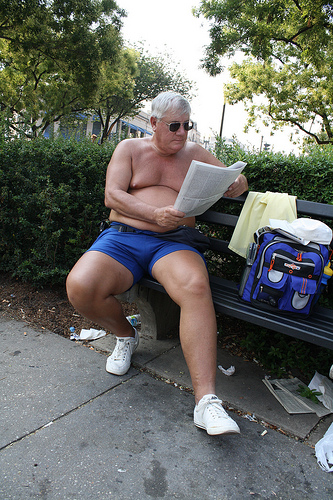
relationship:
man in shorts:
[65, 90, 249, 437] [85, 220, 207, 284]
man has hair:
[65, 90, 249, 437] [149, 89, 189, 117]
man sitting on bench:
[65, 90, 249, 437] [136, 200, 329, 342]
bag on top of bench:
[239, 219, 328, 318] [136, 200, 329, 342]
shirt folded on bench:
[226, 189, 298, 259] [136, 200, 329, 342]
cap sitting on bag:
[271, 218, 331, 244] [239, 219, 328, 318]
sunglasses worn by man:
[154, 117, 195, 131] [65, 90, 249, 437]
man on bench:
[65, 90, 249, 437] [136, 200, 329, 342]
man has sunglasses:
[65, 90, 249, 437] [154, 117, 195, 131]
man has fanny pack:
[65, 90, 249, 437] [102, 220, 210, 249]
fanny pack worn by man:
[102, 220, 210, 249] [65, 90, 249, 437]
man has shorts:
[65, 90, 249, 437] [85, 220, 207, 284]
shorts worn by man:
[85, 220, 207, 284] [65, 90, 249, 437]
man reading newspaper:
[65, 90, 249, 437] [171, 158, 249, 219]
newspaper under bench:
[261, 371, 332, 419] [136, 200, 329, 342]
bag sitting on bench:
[239, 219, 328, 318] [136, 200, 329, 342]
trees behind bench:
[193, 0, 333, 152] [136, 200, 329, 342]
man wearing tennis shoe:
[65, 90, 249, 437] [191, 393, 238, 435]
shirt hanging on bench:
[226, 189, 298, 259] [136, 200, 329, 342]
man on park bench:
[65, 90, 249, 437] [136, 200, 329, 342]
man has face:
[65, 90, 249, 437] [156, 113, 188, 150]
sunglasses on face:
[154, 117, 195, 131] [156, 113, 188, 150]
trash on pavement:
[219, 363, 332, 417] [3, 279, 332, 498]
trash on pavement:
[63, 322, 106, 344] [3, 279, 332, 498]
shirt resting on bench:
[226, 189, 298, 259] [136, 200, 329, 342]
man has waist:
[65, 90, 249, 437] [92, 216, 212, 251]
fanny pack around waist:
[102, 220, 210, 249] [92, 216, 212, 251]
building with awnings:
[9, 87, 153, 139] [47, 111, 147, 136]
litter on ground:
[261, 371, 332, 419] [3, 279, 332, 498]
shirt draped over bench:
[226, 189, 298, 259] [136, 200, 329, 342]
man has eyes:
[65, 90, 249, 437] [168, 124, 191, 130]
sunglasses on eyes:
[154, 117, 195, 131] [168, 124, 191, 130]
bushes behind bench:
[1, 141, 332, 370] [136, 200, 329, 342]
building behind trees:
[9, 87, 153, 139] [0, 3, 173, 136]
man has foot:
[65, 90, 249, 437] [191, 392, 241, 437]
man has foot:
[65, 90, 249, 437] [103, 332, 142, 378]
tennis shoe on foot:
[191, 393, 238, 435] [191, 392, 241, 437]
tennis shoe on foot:
[105, 332, 142, 375] [103, 332, 142, 378]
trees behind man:
[193, 0, 333, 152] [65, 90, 249, 437]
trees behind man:
[0, 3, 173, 136] [65, 90, 249, 437]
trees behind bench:
[0, 3, 173, 136] [136, 200, 329, 342]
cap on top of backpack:
[271, 218, 331, 244] [239, 219, 328, 318]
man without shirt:
[65, 90, 249, 437] [226, 189, 298, 259]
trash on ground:
[219, 363, 332, 417] [3, 279, 332, 498]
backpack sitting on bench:
[239, 219, 328, 318] [136, 200, 329, 342]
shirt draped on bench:
[226, 189, 298, 259] [136, 200, 329, 342]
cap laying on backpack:
[271, 218, 331, 244] [239, 219, 328, 318]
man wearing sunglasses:
[65, 90, 249, 437] [154, 117, 195, 131]